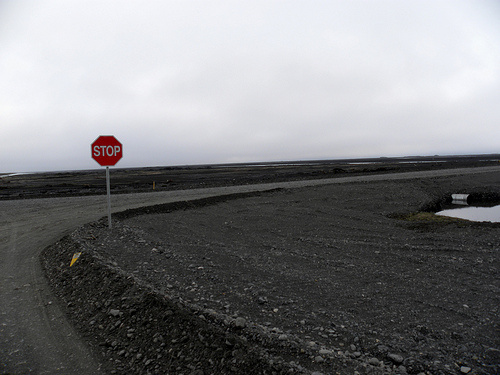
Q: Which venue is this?
A: This is a road.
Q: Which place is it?
A: It is a road.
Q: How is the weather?
A: It is cloudy.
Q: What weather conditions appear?
A: It is cloudy.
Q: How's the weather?
A: It is cloudy.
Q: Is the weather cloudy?
A: Yes, it is cloudy.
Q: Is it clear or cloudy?
A: It is cloudy.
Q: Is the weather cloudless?
A: No, it is cloudy.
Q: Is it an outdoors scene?
A: Yes, it is outdoors.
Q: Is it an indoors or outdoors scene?
A: It is outdoors.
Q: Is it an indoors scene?
A: No, it is outdoors.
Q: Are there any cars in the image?
A: No, there are no cars.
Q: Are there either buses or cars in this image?
A: No, there are no cars or buses.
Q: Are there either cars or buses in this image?
A: No, there are no cars or buses.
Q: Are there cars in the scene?
A: No, there are no cars.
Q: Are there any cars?
A: No, there are no cars.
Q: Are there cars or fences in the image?
A: No, there are no cars or fences.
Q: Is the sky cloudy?
A: Yes, the sky is cloudy.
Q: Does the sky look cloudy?
A: Yes, the sky is cloudy.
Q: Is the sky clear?
A: No, the sky is cloudy.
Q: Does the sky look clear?
A: No, the sky is cloudy.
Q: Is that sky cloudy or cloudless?
A: The sky is cloudy.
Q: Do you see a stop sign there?
A: Yes, there is a stop sign.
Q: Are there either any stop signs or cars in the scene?
A: Yes, there is a stop sign.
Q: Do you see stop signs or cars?
A: Yes, there is a stop sign.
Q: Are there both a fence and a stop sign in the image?
A: No, there is a stop sign but no fences.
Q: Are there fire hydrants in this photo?
A: No, there are no fire hydrants.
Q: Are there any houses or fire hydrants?
A: No, there are no fire hydrants or houses.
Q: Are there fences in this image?
A: No, there are no fences.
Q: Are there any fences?
A: No, there are no fences.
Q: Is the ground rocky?
A: Yes, the ground is rocky.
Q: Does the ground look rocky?
A: Yes, the ground is rocky.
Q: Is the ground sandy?
A: No, the ground is rocky.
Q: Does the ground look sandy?
A: No, the ground is rocky.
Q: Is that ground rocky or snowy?
A: The ground is rocky.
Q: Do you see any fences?
A: No, there are no fences.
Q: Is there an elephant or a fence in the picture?
A: No, there are no fences or elephants.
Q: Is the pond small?
A: Yes, the pond is small.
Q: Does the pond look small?
A: Yes, the pond is small.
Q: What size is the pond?
A: The pond is small.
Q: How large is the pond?
A: The pond is small.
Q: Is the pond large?
A: No, the pond is small.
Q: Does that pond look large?
A: No, the pond is small.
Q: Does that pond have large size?
A: No, the pond is small.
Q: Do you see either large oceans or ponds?
A: No, there is a pond but it is small.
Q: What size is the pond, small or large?
A: The pond is small.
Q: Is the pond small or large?
A: The pond is small.